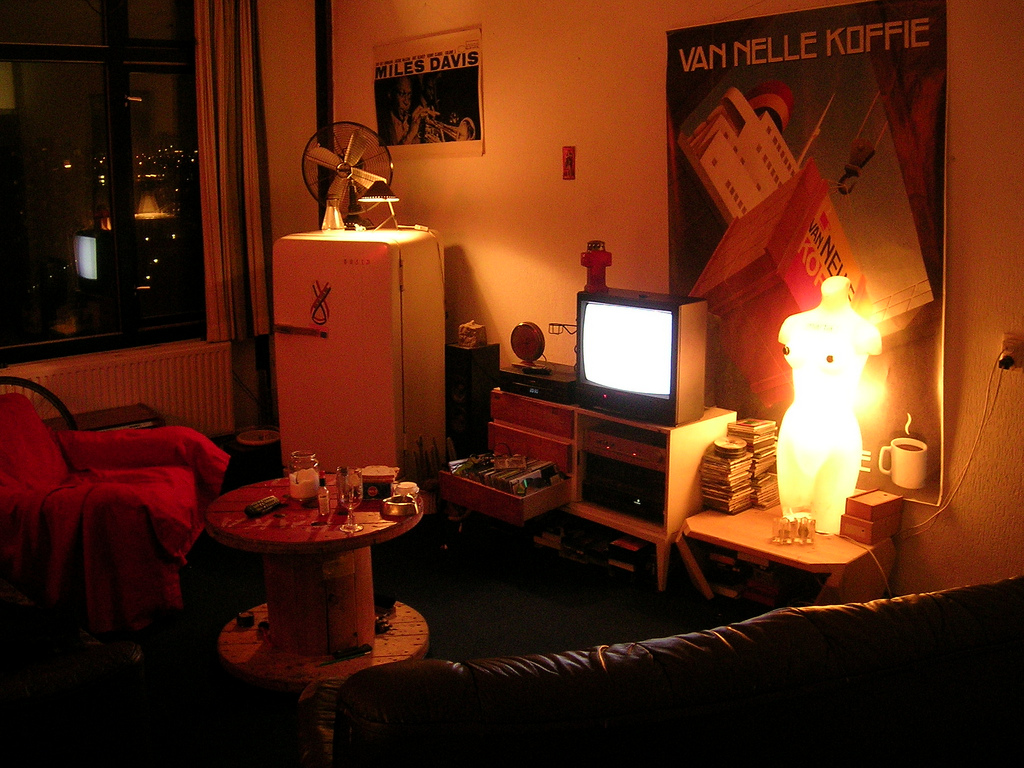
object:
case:
[339, 509, 364, 533]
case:
[699, 449, 754, 466]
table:
[681, 497, 895, 605]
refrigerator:
[271, 226, 446, 487]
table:
[203, 470, 427, 694]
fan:
[299, 121, 397, 231]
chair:
[0, 383, 228, 635]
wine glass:
[336, 466, 364, 533]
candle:
[288, 468, 320, 502]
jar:
[287, 449, 322, 502]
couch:
[332, 573, 1024, 766]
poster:
[372, 22, 489, 157]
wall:
[326, 0, 1022, 613]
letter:
[710, 44, 726, 70]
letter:
[827, 30, 844, 56]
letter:
[679, 48, 695, 72]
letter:
[799, 30, 821, 60]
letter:
[884, 21, 901, 51]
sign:
[666, 1, 950, 511]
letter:
[846, 28, 862, 55]